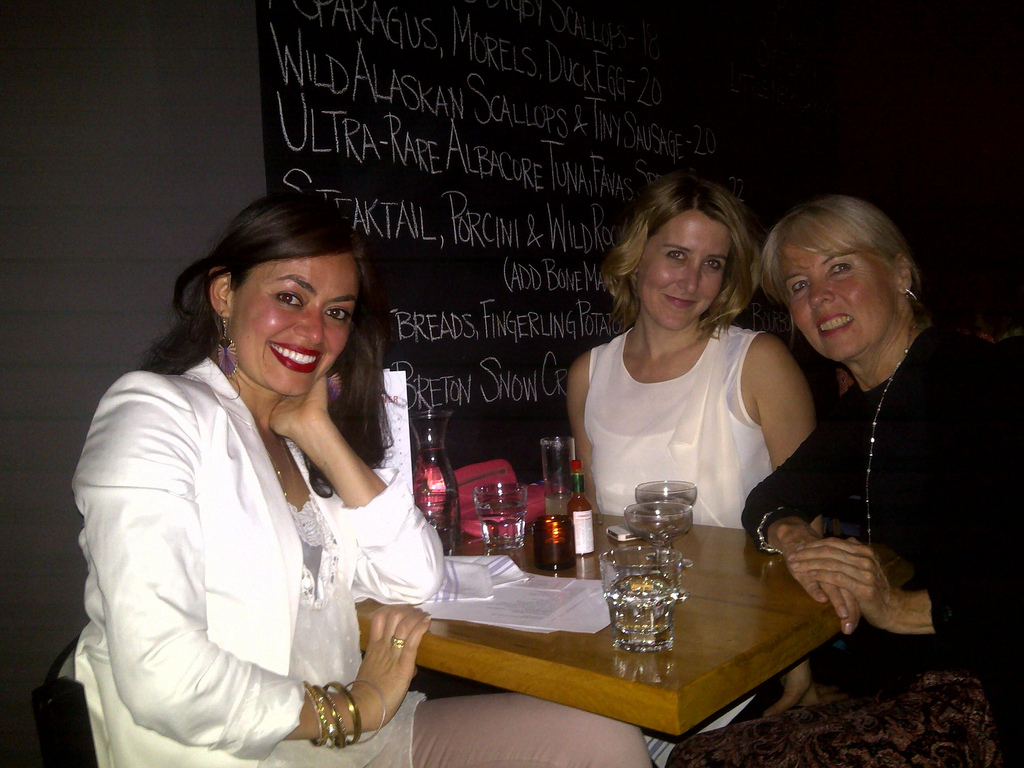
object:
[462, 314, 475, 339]
letter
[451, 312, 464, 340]
letter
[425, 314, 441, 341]
letter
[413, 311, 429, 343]
letter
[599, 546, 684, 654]
glass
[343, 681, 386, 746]
bracelets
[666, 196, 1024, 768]
woman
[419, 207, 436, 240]
letter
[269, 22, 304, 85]
letter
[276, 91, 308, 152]
letter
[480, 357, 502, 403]
letter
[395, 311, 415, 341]
letter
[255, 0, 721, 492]
sign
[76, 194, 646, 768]
woman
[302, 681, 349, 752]
bracelet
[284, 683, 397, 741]
wrist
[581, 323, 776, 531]
shirt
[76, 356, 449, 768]
white jacket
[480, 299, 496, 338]
letter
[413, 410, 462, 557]
clear vase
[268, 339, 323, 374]
lips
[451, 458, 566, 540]
fire hydrant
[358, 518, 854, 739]
table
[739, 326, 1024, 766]
sweater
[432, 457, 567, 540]
purse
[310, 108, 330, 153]
letter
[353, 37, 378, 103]
letter